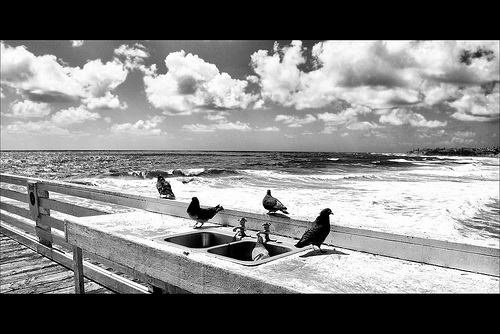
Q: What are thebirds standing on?
A: A wooden counter.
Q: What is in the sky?
A: Clouds.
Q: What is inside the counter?
A: A sink.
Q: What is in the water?
A: Waves.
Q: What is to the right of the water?
A: Land.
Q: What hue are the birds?
A: Black.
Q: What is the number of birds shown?
A: 5.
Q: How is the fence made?
A: Of wood.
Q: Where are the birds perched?
A: A fence.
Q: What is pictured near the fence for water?
A: A sink.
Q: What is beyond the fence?
A: Water.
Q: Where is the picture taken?
A: Beachside.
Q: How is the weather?
A: Clear and sunny.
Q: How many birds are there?
A: 5.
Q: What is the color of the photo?
A: Black and white.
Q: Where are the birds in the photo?
A: Standing on the side of the rail.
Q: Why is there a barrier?
A: To stop the water.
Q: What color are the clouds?
A: White.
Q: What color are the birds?
A: Black.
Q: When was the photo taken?
A: Day time.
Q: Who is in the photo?
A: No one.